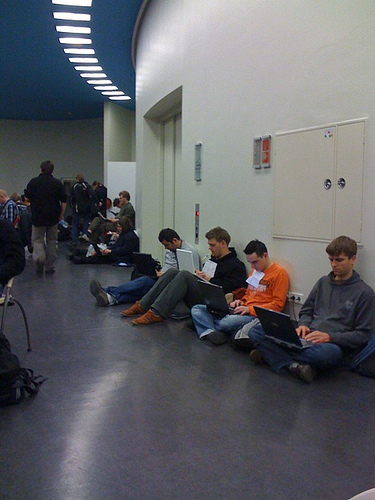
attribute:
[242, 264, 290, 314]
shirt — orange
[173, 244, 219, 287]
laptop — white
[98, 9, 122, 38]
ceiling — blue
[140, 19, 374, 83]
wall — white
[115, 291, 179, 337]
shoe — brown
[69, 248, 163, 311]
jeans — blue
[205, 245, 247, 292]
hoodie — black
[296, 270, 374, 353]
hoodie — gray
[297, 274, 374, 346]
shirt — gray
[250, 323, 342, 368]
jeans — blue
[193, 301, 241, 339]
jeans — blue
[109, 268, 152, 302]
jeans — blue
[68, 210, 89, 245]
jeans — blue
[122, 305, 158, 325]
shoes — orange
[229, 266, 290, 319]
shirt — orange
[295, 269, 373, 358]
grey jacket — gray 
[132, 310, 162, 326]
shoe — brown 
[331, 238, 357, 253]
hair — brown, short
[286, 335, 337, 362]
leg — crossed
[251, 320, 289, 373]
leg — crossed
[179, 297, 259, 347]
jeans — blue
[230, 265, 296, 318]
shirt — orange